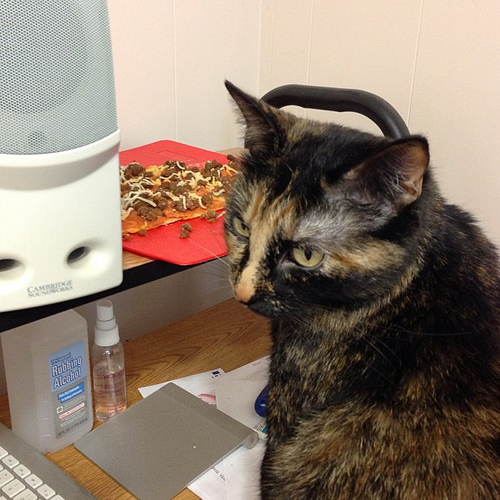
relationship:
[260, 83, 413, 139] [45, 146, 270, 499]
bar on desk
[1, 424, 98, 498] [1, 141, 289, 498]
computer keyboard on desk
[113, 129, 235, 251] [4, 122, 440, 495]
food on desk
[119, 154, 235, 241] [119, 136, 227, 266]
food on plate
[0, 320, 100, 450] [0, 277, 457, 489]
alcohol on desk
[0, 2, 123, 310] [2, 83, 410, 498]
computer speaker on desk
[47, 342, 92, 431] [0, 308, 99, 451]
label on bottle